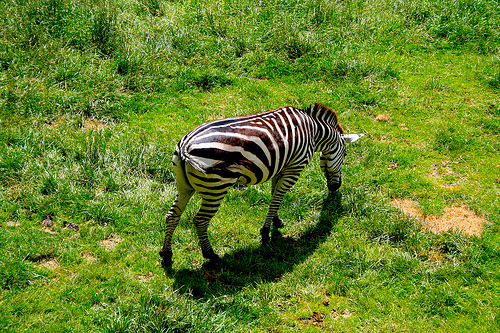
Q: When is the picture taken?
A: Daytime.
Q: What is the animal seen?
A: Zebra.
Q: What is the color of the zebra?
A: Black and white.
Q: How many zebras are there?
A: One.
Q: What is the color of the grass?
A: Green.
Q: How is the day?
A: Sunny.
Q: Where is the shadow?
A: In the ground.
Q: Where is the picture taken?
A: In a zoo.